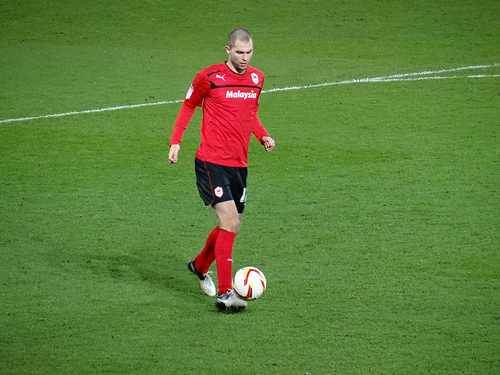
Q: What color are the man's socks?
A: Red.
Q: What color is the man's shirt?
A: Red.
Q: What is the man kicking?
A: A soccer ball.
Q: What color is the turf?
A: Green.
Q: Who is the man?
A: A professional soccer player.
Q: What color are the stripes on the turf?
A: White.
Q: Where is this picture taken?
A: On a soccer field.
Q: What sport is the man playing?
A: Soccer.